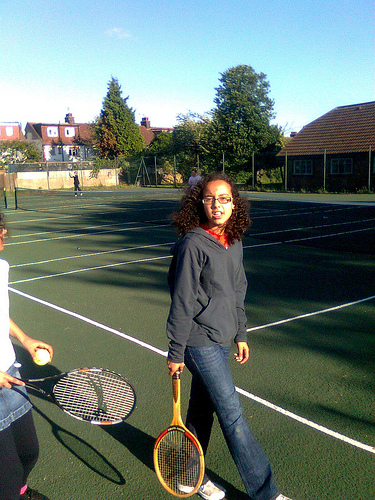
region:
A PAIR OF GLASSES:
[190, 192, 236, 207]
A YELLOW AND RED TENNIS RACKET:
[147, 361, 207, 498]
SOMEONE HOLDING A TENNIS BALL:
[17, 330, 58, 368]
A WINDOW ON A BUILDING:
[283, 150, 322, 182]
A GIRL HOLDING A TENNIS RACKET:
[148, 168, 277, 492]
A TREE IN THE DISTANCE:
[208, 52, 279, 180]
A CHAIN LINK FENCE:
[251, 143, 369, 197]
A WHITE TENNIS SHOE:
[172, 465, 231, 498]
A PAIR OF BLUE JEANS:
[162, 333, 307, 498]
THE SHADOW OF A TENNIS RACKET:
[24, 396, 134, 490]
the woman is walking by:
[156, 173, 286, 497]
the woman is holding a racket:
[153, 361, 209, 497]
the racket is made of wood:
[155, 367, 205, 497]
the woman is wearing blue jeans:
[174, 339, 280, 499]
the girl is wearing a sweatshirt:
[158, 224, 251, 350]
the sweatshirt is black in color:
[170, 227, 251, 355]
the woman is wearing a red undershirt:
[204, 226, 230, 249]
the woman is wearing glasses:
[202, 194, 230, 203]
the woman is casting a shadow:
[8, 336, 264, 496]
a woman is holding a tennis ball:
[8, 316, 53, 367]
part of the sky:
[183, 10, 239, 44]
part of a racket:
[160, 458, 190, 492]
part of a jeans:
[234, 440, 270, 476]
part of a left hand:
[232, 341, 250, 362]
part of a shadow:
[73, 437, 126, 481]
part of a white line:
[330, 414, 358, 450]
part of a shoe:
[208, 483, 220, 496]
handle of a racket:
[167, 384, 188, 417]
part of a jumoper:
[210, 283, 241, 334]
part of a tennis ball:
[27, 349, 46, 374]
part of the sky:
[146, 16, 189, 58]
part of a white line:
[303, 408, 345, 441]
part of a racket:
[170, 462, 200, 493]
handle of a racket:
[172, 394, 189, 422]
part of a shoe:
[211, 485, 218, 495]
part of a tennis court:
[299, 361, 342, 406]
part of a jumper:
[214, 297, 240, 325]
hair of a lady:
[232, 203, 249, 228]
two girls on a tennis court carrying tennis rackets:
[0, 173, 291, 498]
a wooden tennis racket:
[150, 371, 213, 498]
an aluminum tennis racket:
[24, 366, 135, 426]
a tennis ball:
[30, 345, 48, 360]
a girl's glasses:
[196, 196, 231, 201]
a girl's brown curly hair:
[171, 184, 196, 230]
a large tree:
[189, 63, 274, 168]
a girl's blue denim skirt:
[0, 386, 30, 426]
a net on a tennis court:
[23, 183, 155, 216]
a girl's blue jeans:
[189, 352, 280, 456]